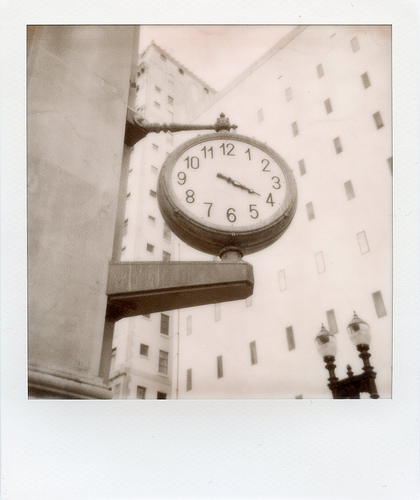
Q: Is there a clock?
A: Yes, there is a clock.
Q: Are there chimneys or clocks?
A: Yes, there is a clock.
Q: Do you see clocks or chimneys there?
A: Yes, there is a clock.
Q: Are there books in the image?
A: No, there are no books.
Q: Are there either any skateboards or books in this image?
A: No, there are no books or skateboards.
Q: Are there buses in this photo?
A: No, there are no buses.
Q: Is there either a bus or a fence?
A: No, there are no buses or fences.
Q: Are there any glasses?
A: No, there are no glasses.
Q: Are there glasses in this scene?
A: No, there are no glasses.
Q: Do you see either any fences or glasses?
A: No, there are no glasses or fences.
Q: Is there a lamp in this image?
A: Yes, there is a lamp.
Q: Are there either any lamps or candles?
A: Yes, there is a lamp.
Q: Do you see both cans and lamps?
A: No, there is a lamp but no cans.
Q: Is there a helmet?
A: No, there are no helmets.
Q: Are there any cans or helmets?
A: No, there are no helmets or cans.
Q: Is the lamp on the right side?
A: Yes, the lamp is on the right of the image.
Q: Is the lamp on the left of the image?
A: No, the lamp is on the right of the image.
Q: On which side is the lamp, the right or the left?
A: The lamp is on the right of the image.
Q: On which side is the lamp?
A: The lamp is on the right of the image.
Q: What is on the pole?
A: The lamp is on the pole.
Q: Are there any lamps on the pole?
A: Yes, there is a lamp on the pole.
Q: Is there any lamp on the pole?
A: Yes, there is a lamp on the pole.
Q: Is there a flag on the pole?
A: No, there is a lamp on the pole.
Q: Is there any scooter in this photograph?
A: No, there are no scooters.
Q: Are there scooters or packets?
A: No, there are no scooters or packets.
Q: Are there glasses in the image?
A: No, there are no glasses.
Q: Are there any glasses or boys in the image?
A: No, there are no glasses or boys.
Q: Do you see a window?
A: Yes, there is a window.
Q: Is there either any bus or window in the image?
A: Yes, there is a window.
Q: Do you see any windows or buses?
A: Yes, there is a window.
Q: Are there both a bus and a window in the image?
A: No, there is a window but no buses.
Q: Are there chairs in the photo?
A: No, there are no chairs.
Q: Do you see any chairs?
A: No, there are no chairs.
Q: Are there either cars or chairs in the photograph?
A: No, there are no chairs or cars.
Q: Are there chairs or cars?
A: No, there are no chairs or cars.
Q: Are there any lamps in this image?
A: Yes, there is a lamp.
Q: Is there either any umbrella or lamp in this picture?
A: Yes, there is a lamp.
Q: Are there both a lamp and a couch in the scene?
A: No, there is a lamp but no couches.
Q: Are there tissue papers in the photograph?
A: No, there are no tissue papers.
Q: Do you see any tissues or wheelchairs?
A: No, there are no tissues or wheelchairs.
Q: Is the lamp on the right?
A: Yes, the lamp is on the right of the image.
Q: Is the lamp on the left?
A: No, the lamp is on the right of the image.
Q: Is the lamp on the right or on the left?
A: The lamp is on the right of the image.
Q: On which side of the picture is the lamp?
A: The lamp is on the right of the image.